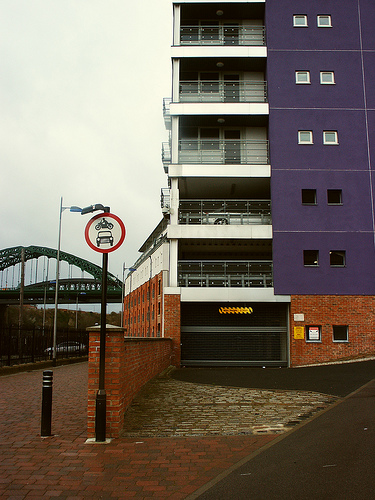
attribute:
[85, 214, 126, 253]
sign — regarding street, about street, metal, a circle, circle, outdoors, for traffic, about traffic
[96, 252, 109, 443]
pole — metal, black, for safety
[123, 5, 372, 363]
building — purple, brown, white, to side of garage, six stories, high, apartment type, purple sided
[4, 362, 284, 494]
ground — made of bricks, made of brick, brick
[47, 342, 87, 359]
car — silver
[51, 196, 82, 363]
light — for street, in the sky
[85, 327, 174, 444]
wall — made of bricks, brick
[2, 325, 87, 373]
garage — for parking, to side of back wall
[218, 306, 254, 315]
sign — about hazard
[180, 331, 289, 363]
door — for garage, leading to parking, entrance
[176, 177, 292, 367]
garage — for parking, brick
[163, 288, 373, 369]
first floor — made of bricks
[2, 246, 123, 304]
bridge — arched, metal, green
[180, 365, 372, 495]
ramp — green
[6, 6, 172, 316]
sky — cloudy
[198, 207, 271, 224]
car — silver, parked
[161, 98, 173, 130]
balcony — open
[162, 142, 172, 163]
balcony — open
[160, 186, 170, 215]
balcony — open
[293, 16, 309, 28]
window — white framed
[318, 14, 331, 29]
window — white framed